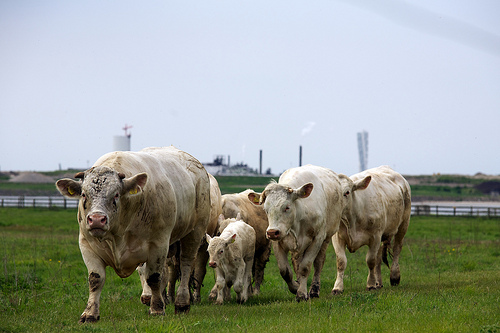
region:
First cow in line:
[31, 142, 203, 327]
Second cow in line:
[205, 217, 260, 309]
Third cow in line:
[248, 163, 343, 305]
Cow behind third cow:
[331, 170, 420, 297]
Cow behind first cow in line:
[213, 179, 247, 224]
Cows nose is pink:
[199, 257, 224, 272]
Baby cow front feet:
[210, 283, 260, 305]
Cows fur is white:
[313, 169, 334, 200]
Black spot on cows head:
[90, 168, 108, 200]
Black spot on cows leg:
[81, 266, 106, 295]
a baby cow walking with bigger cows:
[197, 217, 259, 302]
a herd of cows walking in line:
[63, 147, 417, 322]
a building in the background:
[96, 127, 306, 180]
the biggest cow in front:
[64, 144, 215, 319]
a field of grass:
[11, 205, 499, 330]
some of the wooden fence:
[3, 194, 80, 212]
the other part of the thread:
[407, 201, 499, 221]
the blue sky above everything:
[5, 10, 497, 142]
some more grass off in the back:
[412, 172, 497, 202]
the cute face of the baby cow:
[203, 232, 235, 269]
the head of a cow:
[51, 162, 152, 245]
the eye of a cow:
[110, 188, 124, 203]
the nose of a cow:
[82, 207, 114, 230]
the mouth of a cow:
[82, 222, 112, 234]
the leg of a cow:
[74, 234, 112, 312]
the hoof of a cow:
[74, 302, 106, 327]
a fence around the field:
[0, 196, 497, 215]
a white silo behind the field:
[108, 131, 136, 155]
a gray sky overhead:
[0, 0, 499, 173]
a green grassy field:
[0, 204, 499, 331]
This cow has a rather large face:
[69, 164, 137, 249]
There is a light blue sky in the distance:
[393, 37, 441, 89]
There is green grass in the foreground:
[428, 261, 460, 306]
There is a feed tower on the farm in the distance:
[108, 125, 135, 154]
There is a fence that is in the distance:
[11, 190, 50, 234]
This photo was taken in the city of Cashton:
[83, 63, 390, 320]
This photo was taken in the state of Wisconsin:
[115, 46, 355, 302]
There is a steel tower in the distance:
[253, 145, 270, 165]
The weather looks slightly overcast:
[202, 10, 257, 77]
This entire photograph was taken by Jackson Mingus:
[80, 37, 385, 315]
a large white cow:
[50, 145, 210, 325]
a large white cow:
[244, 160, 346, 304]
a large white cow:
[327, 164, 409, 292]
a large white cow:
[207, 188, 272, 290]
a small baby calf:
[206, 219, 253, 304]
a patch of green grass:
[7, 205, 497, 331]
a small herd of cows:
[55, 146, 412, 324]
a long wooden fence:
[1, 196, 498, 221]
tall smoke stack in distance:
[290, 116, 312, 167]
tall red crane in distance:
[115, 121, 137, 138]